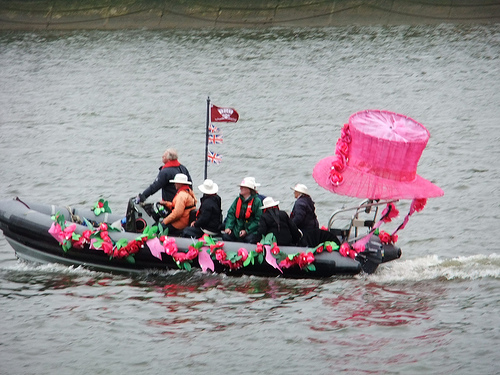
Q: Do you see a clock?
A: No, there are no clocks.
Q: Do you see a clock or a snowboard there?
A: No, there are no clocks or snowboards.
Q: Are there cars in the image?
A: No, there are no cars.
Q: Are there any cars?
A: No, there are no cars.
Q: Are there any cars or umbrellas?
A: No, there are no cars or umbrellas.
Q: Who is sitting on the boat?
A: The people are sitting on the boat.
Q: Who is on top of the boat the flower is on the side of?
A: The people are on top of the boat.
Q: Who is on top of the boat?
A: The people are on top of the boat.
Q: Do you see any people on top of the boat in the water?
A: Yes, there are people on top of the boat.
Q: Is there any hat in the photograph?
A: Yes, there is a hat.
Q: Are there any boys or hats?
A: Yes, there is a hat.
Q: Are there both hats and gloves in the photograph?
A: No, there is a hat but no gloves.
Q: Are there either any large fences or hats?
A: Yes, there is a large hat.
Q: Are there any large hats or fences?
A: Yes, there is a large hat.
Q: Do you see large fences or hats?
A: Yes, there is a large hat.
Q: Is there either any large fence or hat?
A: Yes, there is a large hat.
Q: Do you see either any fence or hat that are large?
A: Yes, the hat is large.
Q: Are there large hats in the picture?
A: Yes, there is a large hat.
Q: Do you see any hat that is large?
A: Yes, there is a hat that is large.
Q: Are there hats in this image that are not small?
A: Yes, there is a large hat.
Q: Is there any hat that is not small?
A: Yes, there is a large hat.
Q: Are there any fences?
A: No, there are no fences.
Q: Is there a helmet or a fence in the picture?
A: No, there are no fences or helmets.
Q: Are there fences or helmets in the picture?
A: No, there are no fences or helmets.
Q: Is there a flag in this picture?
A: Yes, there is a flag.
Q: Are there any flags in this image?
A: Yes, there is a flag.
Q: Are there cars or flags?
A: Yes, there is a flag.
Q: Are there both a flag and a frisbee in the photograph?
A: No, there is a flag but no frisbees.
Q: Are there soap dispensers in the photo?
A: No, there are no soap dispensers.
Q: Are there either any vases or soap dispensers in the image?
A: No, there are no soap dispensers or vases.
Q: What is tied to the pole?
A: The flag is tied to the pole.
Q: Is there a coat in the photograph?
A: Yes, there is a coat.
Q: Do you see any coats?
A: Yes, there is a coat.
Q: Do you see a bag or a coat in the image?
A: Yes, there is a coat.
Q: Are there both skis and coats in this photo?
A: No, there is a coat but no skis.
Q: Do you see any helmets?
A: No, there are no helmets.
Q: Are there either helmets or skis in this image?
A: No, there are no helmets or skis.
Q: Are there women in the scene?
A: Yes, there is a woman.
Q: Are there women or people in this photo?
A: Yes, there is a woman.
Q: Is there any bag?
A: No, there are no bags.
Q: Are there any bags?
A: No, there are no bags.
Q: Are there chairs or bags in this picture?
A: No, there are no bags or chairs.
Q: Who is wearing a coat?
A: The woman is wearing a coat.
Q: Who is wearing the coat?
A: The woman is wearing a coat.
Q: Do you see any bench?
A: No, there are no benches.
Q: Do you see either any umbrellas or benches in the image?
A: No, there are no benches or umbrellas.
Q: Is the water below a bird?
A: No, the water is below a boat.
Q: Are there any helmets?
A: No, there are no helmets.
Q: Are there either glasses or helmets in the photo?
A: No, there are no helmets or glasses.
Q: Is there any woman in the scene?
A: Yes, there is a woman.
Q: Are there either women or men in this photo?
A: Yes, there is a woman.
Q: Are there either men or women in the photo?
A: Yes, there is a woman.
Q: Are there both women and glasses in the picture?
A: No, there is a woman but no glasses.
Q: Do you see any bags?
A: No, there are no bags.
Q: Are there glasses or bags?
A: No, there are no bags or glasses.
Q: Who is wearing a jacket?
A: The woman is wearing a jacket.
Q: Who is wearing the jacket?
A: The woman is wearing a jacket.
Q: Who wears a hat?
A: The woman wears a hat.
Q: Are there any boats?
A: Yes, there is a boat.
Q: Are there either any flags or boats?
A: Yes, there is a boat.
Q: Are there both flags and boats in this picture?
A: Yes, there are both a boat and a flag.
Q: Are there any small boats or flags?
A: Yes, there is a small boat.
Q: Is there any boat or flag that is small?
A: Yes, the boat is small.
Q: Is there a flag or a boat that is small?
A: Yes, the boat is small.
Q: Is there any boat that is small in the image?
A: Yes, there is a small boat.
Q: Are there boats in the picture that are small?
A: Yes, there is a boat that is small.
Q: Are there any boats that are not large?
A: Yes, there is a small boat.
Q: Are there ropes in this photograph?
A: No, there are no ropes.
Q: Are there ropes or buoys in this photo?
A: No, there are no ropes or buoys.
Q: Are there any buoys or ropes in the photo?
A: No, there are no ropes or buoys.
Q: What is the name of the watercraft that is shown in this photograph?
A: The watercraft is a boat.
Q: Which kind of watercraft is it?
A: The watercraft is a boat.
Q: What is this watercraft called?
A: That is a boat.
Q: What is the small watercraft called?
A: The watercraft is a boat.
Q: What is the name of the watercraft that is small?
A: The watercraft is a boat.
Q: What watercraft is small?
A: The watercraft is a boat.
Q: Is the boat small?
A: Yes, the boat is small.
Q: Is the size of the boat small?
A: Yes, the boat is small.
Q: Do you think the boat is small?
A: Yes, the boat is small.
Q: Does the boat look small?
A: Yes, the boat is small.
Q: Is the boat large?
A: No, the boat is small.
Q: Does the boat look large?
A: No, the boat is small.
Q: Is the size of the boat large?
A: No, the boat is small.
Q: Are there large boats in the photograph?
A: No, there is a boat but it is small.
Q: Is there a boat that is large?
A: No, there is a boat but it is small.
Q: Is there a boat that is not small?
A: No, there is a boat but it is small.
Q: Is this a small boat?
A: Yes, this is a small boat.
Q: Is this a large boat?
A: No, this is a small boat.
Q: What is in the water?
A: The boat is in the water.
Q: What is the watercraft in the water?
A: The watercraft is a boat.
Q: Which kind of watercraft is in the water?
A: The watercraft is a boat.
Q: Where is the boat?
A: The boat is in the water.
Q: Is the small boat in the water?
A: Yes, the boat is in the water.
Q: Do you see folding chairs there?
A: No, there are no folding chairs.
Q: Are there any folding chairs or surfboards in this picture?
A: No, there are no folding chairs or surfboards.